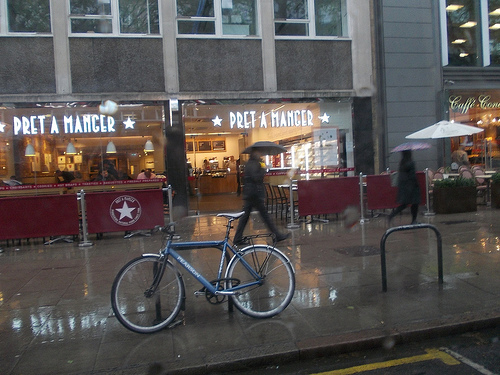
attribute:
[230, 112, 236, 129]
letter — white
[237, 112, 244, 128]
letter — white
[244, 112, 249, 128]
letter — white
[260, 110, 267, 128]
letter — white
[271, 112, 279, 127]
letter — white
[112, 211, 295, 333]
bicycle — blue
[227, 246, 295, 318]
wheel — black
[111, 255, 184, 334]
wheel — black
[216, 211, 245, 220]
seat — black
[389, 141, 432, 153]
umbrella — purple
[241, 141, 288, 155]
umbrella — black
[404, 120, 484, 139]
umbrella — white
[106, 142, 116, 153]
lamp — white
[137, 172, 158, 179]
shirt — pink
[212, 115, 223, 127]
star — white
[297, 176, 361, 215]
wall — red